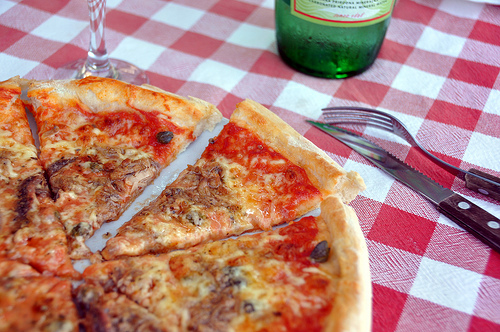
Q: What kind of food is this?
A: Pizza.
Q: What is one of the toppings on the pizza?
A: Cheese.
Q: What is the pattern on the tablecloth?
A: Checkered.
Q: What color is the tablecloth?
A: Red and white.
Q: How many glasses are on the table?
A: One.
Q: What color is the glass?
A: Green.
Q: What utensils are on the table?
A: Knife and fork.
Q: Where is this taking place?
A: At a restaurant.